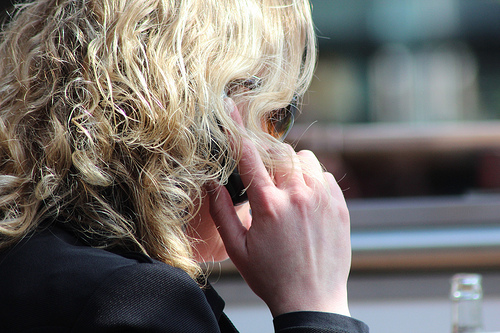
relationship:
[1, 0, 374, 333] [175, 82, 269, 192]
person talking on phone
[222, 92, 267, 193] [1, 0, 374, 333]
finger of a person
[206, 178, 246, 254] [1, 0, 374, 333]
finger of a person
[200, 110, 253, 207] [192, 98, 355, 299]
cellphone in hand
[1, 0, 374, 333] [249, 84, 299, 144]
person wearing glasses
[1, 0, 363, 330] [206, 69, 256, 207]
person holding phone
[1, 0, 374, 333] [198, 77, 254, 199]
person talking on phone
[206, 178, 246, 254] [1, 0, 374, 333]
finger of person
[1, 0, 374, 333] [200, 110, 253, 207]
person has cellphone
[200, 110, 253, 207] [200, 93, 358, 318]
cellphone in hand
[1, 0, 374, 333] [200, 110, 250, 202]
person has cellphone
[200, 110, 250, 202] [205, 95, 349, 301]
cellphone in hand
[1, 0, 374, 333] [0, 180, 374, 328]
person wearing jacket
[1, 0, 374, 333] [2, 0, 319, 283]
person has hair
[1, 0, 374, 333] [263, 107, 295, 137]
person wearing sunglasses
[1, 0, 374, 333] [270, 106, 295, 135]
person wearing sunglasses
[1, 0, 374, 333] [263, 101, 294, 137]
person wearing sunglasses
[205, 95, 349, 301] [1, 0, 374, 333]
hand of person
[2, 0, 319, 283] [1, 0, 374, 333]
hair on person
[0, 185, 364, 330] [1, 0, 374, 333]
coat on person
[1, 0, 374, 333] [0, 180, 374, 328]
person with jacket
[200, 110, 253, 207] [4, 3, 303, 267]
cellphone against head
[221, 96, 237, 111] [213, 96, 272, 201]
fingernail on finger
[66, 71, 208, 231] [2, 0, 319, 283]
curls in hair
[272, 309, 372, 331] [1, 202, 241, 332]
cuff of shirt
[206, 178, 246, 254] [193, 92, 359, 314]
finger of woman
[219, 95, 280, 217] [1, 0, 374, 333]
finger of person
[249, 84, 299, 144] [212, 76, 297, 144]
glasses on face